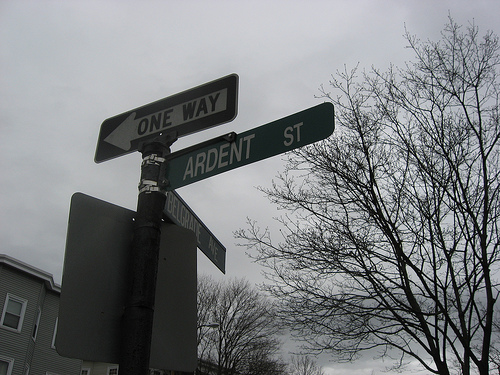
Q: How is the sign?
A: Black and white.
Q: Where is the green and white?
A: Sign.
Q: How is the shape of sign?
A: Rectangle.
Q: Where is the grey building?
A: In corner.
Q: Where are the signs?
A: Post.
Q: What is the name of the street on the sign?
A: Ardent.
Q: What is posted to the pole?
A: Sign.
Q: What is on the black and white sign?
A: Arrow.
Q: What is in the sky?
A: Cloud.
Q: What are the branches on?
A: Tree.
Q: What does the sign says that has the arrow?
A: One way.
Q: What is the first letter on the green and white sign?
A: A.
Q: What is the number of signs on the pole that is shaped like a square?
A: One.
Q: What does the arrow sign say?
A: One way.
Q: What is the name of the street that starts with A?
A: Ardent.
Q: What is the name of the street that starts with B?
A: Belgrade.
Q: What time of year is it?
A: Winter.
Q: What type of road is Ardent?
A: Street.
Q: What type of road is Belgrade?
A: Avenue.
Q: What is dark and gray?
A: Sky.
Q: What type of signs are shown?
A: Street.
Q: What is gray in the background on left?
A: House.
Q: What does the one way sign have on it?
A: Arrow.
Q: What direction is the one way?
A: Left.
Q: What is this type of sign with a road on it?
A: Street sign.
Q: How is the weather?
A: Rainy.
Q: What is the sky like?
A: Overcast.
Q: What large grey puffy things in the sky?
A: Clouds.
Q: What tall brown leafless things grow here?
A: Trees.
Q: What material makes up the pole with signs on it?
A: Metal.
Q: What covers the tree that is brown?
A: Bark.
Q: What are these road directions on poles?
A: Signs.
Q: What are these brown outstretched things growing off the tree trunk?
A: Branches.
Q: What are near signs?
A: Trees.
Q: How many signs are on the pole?
A: 4.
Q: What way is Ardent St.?
A: One way.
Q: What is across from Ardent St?
A: Belgrade Ave.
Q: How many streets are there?
A: 2.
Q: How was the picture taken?
A: Facing up.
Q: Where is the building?
A: Behind street sign.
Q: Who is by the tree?
A: No one.